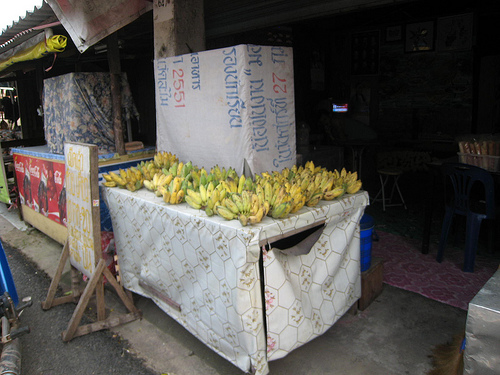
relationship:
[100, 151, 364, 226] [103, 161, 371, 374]
bananas on top of table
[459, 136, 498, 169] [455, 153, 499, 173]
bread inside basket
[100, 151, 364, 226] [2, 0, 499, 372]
bananas located at market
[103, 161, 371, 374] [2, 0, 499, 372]
table located in market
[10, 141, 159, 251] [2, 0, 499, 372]
table located in market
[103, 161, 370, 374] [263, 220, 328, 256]
table has rip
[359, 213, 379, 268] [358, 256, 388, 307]
pail on top of box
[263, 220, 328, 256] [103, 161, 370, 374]
rip located in table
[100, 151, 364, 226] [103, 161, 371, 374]
bananas displayed on table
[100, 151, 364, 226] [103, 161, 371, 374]
bananas located on table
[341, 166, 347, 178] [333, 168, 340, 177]
banana next to banana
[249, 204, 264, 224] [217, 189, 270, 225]
banana in a bunch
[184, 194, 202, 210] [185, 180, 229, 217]
banana in a bunch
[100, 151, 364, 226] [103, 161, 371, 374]
bananas diplayed on table